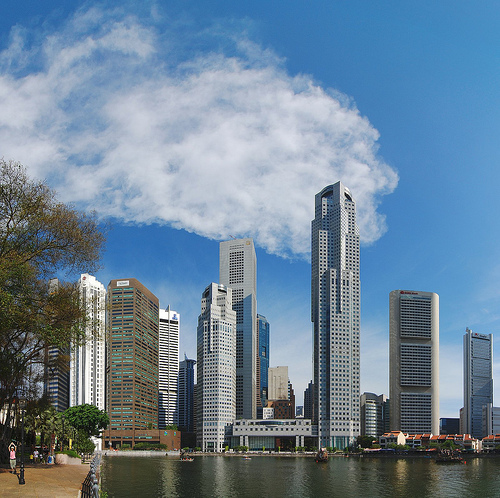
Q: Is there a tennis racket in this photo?
A: No, there are no rackets.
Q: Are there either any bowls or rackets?
A: No, there are no rackets or bowls.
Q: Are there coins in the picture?
A: No, there are no coins.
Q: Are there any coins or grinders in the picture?
A: No, there are no coins or grinders.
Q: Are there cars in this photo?
A: No, there are no cars.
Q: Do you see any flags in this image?
A: No, there are no flags.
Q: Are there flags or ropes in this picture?
A: No, there are no flags or ropes.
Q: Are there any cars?
A: No, there are no cars.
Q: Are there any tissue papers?
A: No, there are no tissue papers.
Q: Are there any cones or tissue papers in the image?
A: No, there are no tissue papers or cones.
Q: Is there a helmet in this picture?
A: No, there are no helmets.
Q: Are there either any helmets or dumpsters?
A: No, there are no helmets or dumpsters.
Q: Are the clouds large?
A: Yes, the clouds are large.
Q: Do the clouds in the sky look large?
A: Yes, the clouds are large.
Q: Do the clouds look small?
A: No, the clouds are large.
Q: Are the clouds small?
A: No, the clouds are large.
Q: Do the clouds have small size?
A: No, the clouds are large.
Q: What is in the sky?
A: The clouds are in the sky.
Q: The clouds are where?
A: The clouds are in the sky.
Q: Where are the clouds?
A: The clouds are in the sky.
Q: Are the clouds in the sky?
A: Yes, the clouds are in the sky.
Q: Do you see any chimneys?
A: No, there are no chimneys.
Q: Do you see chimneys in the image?
A: No, there are no chimneys.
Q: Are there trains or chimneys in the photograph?
A: No, there are no chimneys or trains.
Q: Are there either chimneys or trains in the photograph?
A: No, there are no chimneys or trains.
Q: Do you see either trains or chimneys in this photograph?
A: No, there are no chimneys or trains.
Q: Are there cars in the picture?
A: No, there are no cars.